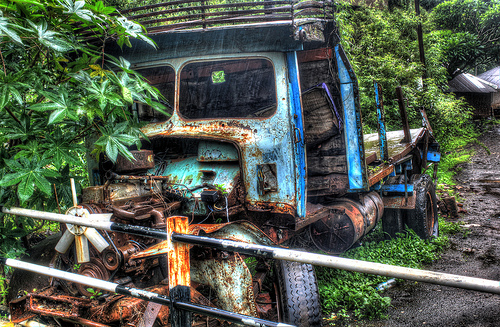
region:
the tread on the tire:
[279, 252, 320, 324]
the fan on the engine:
[47, 225, 118, 262]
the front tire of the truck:
[279, 258, 320, 324]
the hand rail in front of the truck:
[177, 228, 499, 292]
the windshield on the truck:
[180, 59, 275, 116]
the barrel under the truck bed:
[312, 190, 384, 257]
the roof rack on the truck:
[103, 0, 340, 27]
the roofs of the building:
[446, 61, 498, 91]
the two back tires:
[387, 175, 439, 240]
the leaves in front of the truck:
[2, 1, 172, 165]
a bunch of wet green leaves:
[14, 21, 98, 136]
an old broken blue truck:
[134, 9, 438, 323]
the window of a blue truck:
[172, 51, 280, 128]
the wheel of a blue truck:
[270, 271, 337, 325]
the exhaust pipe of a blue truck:
[308, 188, 383, 256]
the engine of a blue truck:
[112, 139, 186, 231]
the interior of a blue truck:
[310, 81, 340, 188]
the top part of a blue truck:
[125, 3, 332, 84]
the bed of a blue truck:
[327, 89, 411, 186]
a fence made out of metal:
[72, 202, 227, 319]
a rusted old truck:
[76, 31, 460, 325]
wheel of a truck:
[232, 242, 332, 324]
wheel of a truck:
[396, 165, 451, 243]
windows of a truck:
[85, 43, 302, 133]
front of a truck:
[93, 108, 298, 269]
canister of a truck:
[319, 163, 399, 258]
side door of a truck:
[269, 46, 361, 223]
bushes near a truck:
[12, 12, 169, 174]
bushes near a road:
[382, 28, 476, 208]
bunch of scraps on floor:
[19, 222, 189, 324]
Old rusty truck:
[84, 1, 430, 320]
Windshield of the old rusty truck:
[117, 56, 282, 126]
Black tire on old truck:
[271, 238, 323, 325]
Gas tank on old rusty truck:
[306, 170, 393, 260]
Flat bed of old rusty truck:
[337, 59, 435, 181]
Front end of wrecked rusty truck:
[68, 147, 283, 325]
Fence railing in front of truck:
[21, 205, 405, 322]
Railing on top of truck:
[131, 0, 323, 41]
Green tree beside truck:
[10, 40, 146, 211]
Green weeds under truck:
[325, 240, 424, 301]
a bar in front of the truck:
[5, 194, 483, 324]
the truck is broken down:
[1, 2, 439, 324]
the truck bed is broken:
[357, 101, 422, 180]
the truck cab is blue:
[123, 36, 370, 227]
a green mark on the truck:
[208, 62, 228, 83]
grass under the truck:
[290, 198, 455, 302]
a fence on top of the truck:
[77, 0, 344, 52]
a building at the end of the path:
[430, 59, 495, 124]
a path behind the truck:
[401, 97, 498, 313]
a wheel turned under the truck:
[267, 256, 321, 324]